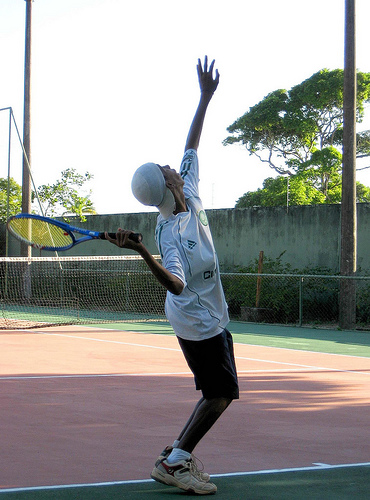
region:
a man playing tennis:
[8, 16, 321, 369]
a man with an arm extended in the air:
[42, 42, 290, 381]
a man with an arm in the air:
[11, 28, 293, 311]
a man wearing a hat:
[23, 60, 347, 381]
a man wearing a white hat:
[96, 63, 279, 239]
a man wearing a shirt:
[40, 42, 337, 353]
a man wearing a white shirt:
[22, 50, 337, 424]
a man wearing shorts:
[21, 74, 343, 494]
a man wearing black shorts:
[49, 110, 348, 487]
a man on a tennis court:
[54, 97, 277, 497]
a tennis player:
[80, 42, 261, 497]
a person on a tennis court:
[22, 52, 305, 498]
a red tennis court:
[0, 302, 367, 495]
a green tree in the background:
[214, 60, 369, 251]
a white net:
[1, 246, 215, 344]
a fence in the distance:
[0, 260, 368, 348]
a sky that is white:
[11, 6, 369, 198]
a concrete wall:
[4, 206, 368, 281]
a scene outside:
[16, 7, 336, 495]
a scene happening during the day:
[10, 4, 369, 448]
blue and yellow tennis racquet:
[7, 212, 142, 249]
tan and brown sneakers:
[153, 444, 215, 496]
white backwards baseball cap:
[130, 164, 176, 213]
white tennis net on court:
[2, 255, 168, 325]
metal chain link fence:
[222, 273, 368, 327]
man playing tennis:
[133, 58, 240, 494]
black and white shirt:
[155, 151, 229, 340]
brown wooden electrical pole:
[339, 0, 357, 327]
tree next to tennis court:
[227, 68, 366, 205]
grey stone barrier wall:
[5, 203, 365, 273]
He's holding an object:
[6, 203, 160, 280]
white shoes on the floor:
[139, 425, 231, 493]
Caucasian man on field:
[112, 149, 256, 246]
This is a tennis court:
[21, 319, 323, 493]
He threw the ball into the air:
[99, 10, 264, 395]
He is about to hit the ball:
[10, 22, 307, 363]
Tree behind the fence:
[213, 53, 366, 227]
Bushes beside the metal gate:
[216, 241, 352, 336]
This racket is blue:
[4, 192, 156, 287]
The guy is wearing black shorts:
[160, 301, 278, 407]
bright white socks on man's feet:
[168, 435, 191, 468]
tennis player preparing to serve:
[5, 47, 247, 497]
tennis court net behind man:
[0, 251, 178, 335]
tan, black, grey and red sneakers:
[151, 448, 221, 497]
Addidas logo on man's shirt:
[183, 237, 198, 251]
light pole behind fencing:
[337, 39, 358, 332]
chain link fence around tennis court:
[1, 261, 368, 338]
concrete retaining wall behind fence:
[0, 193, 367, 283]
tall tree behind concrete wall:
[219, 57, 368, 203]